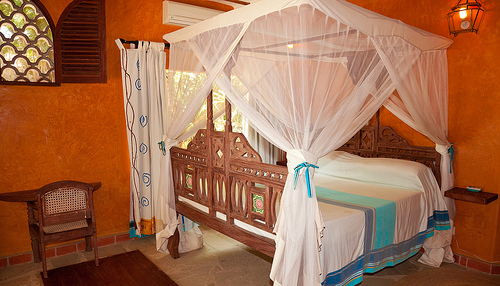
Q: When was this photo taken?
A: During the day.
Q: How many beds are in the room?
A: 1.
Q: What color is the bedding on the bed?
A: Blue and white.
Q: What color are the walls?
A: Orange.